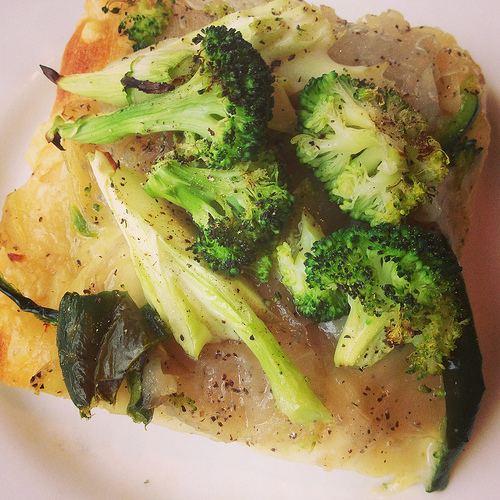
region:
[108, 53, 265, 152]
green colored broccoli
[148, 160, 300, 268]
green colored broccoli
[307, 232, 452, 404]
green colored broccoli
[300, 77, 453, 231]
green colored broccoli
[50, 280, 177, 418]
green colored vegetable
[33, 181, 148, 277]
tan colored meat on plate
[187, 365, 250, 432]
tan colored meat on plate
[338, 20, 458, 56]
tan colored meat on plate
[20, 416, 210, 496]
white plate holding assorted food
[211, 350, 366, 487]
assorted food on white plate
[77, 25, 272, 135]
a piece of seasoned broccoli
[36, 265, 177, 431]
a green cooked vegetable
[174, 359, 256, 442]
seasonings on food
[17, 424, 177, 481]
a white plate under the food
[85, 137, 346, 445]
a cooked green stem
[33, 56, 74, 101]
a burnt end of a vegetable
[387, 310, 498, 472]
dark green rind of a vegetable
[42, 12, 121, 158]
cooked section of food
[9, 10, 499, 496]
a pile of vegetables on a plate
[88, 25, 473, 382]
green pieces of broccoli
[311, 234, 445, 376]
The broccoli is green.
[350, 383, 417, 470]
Seasoning on the meat.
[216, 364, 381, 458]
The meat is pink.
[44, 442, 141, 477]
The table is white.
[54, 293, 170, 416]
Spinach on the meat.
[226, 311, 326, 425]
The stem is green.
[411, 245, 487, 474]
A green pepper on the meat.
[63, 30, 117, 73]
The meat is on bread.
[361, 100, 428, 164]
The broccoli is toasted.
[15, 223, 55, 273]
Cheese on the meat.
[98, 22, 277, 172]
Green broccoli floret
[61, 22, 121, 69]
Portion of a full-sized toasted piece of bread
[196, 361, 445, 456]
Raw meat on toasted bread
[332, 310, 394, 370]
Light green broccoli stalk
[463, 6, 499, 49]
Back ground color is white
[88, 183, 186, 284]
Piece of spinach on toast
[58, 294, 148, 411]
Dark grown leafy vegetable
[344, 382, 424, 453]
Herbs and spices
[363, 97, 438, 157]
Browned section of broccoli floret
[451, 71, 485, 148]
Bean-like green vegetable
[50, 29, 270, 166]
a green broccoli spear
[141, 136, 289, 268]
a green broccoli spear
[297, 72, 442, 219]
a green broccoli spear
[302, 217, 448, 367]
a green broccoli spear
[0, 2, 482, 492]
a cooked piece of meat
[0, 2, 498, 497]
a white ceramic plate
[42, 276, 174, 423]
a piece of spinach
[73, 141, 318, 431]
a green leaf vegetable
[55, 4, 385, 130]
a green leaf vegetable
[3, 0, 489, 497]
a small meal